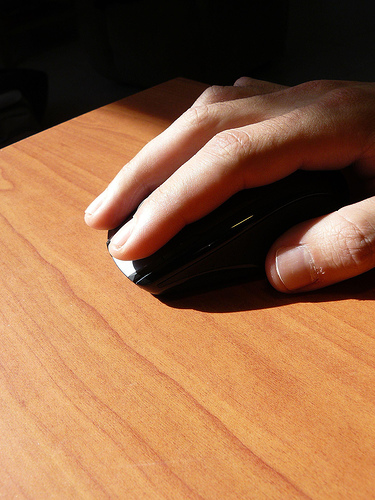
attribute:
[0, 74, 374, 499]
wood — light brown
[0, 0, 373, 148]
background — black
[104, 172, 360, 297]
mouse — silver, black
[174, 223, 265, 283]
mouse — black and gray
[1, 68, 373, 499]
table — wood, wooden, brown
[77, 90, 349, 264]
fingers — white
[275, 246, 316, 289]
fingernail — clipped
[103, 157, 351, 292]
mouse — black